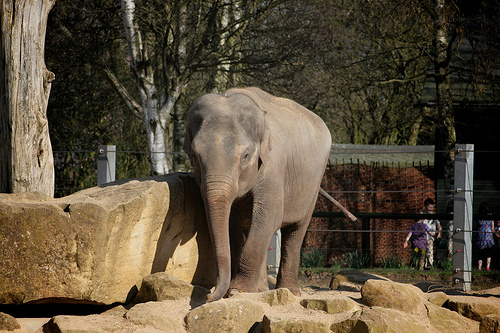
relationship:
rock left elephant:
[363, 278, 429, 315] [184, 74, 348, 287]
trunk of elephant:
[188, 167, 236, 303] [176, 77, 343, 309]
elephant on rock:
[175, 85, 335, 302] [363, 278, 429, 315]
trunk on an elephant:
[188, 167, 236, 303] [176, 77, 343, 309]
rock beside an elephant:
[7, 165, 216, 297] [180, 83, 360, 308]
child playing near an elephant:
[403, 216, 435, 268] [176, 77, 343, 309]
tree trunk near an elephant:
[4, 4, 52, 210] [175, 85, 335, 302]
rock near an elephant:
[355, 279, 462, 310] [162, 76, 347, 257]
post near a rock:
[96, 140, 119, 186] [1, 177, 169, 311]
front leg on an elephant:
[227, 200, 279, 300] [180, 83, 360, 308]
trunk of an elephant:
[188, 167, 236, 303] [186, 87, 332, 301]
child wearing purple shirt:
[407, 208, 434, 268] [412, 221, 429, 247]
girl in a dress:
[473, 200, 496, 272] [475, 215, 494, 256]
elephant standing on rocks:
[175, 85, 335, 302] [106, 254, 479, 331]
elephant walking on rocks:
[152, 111, 360, 286] [250, 282, 425, 309]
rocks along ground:
[16, 274, 498, 330] [0, 262, 498, 330]